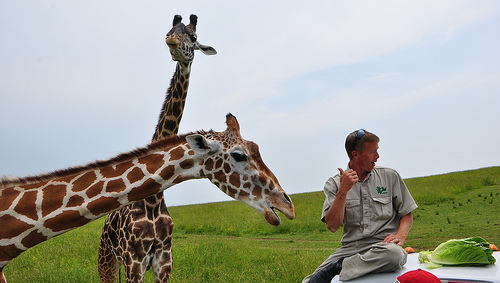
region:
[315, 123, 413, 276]
man's uniform is gray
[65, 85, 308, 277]
giraffe is looking down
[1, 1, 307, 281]
two giraffes on the grass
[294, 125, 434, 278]
a man sitting down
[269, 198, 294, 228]
mouth is open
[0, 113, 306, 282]
head is bent down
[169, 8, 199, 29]
two tiny horns on top of the head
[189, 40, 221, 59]
ear sticking out of the side of the head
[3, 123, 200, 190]
dark hair along the neck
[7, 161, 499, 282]
green grass on the ground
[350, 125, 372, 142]
glasses on the head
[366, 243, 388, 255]
wrinkles on the pants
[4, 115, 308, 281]
Giraffe trying to get some food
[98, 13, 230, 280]
Tall giraffe making a funny face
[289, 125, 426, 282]
Guy pointing his thumb at giraffes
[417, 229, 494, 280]
Large green leaves on the table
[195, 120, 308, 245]
Giraffe with his mouth open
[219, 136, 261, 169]
Small giraffe black eye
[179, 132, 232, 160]
White giraffe ear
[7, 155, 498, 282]
Small hill covered in green grass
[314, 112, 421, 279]
guy has glasses on his head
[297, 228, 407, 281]
Guy with gray pants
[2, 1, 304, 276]
giraffes in the field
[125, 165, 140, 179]
spot on the giraffe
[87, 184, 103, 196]
spot on the giraffe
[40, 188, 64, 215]
spot on the giraffe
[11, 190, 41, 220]
spot on the giraffe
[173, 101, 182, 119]
spot on the giraffe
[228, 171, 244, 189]
spot on the giraffe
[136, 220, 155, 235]
spot on the giraffe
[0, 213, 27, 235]
spot on the giraffe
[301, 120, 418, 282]
Man is pointing at giraffe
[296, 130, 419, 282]
Man wearing gray shirt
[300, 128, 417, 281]
Man wearing gray pants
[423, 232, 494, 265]
Large lettuce piece next to man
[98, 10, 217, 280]
Large giraffe next to man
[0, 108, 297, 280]
Giraffe leaning towards man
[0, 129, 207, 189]
Mane running down neck of giraffe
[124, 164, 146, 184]
Large brown spot on giraffe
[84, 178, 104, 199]
Large brown spot on giraffe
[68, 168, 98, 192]
Large brown spot on giraffe